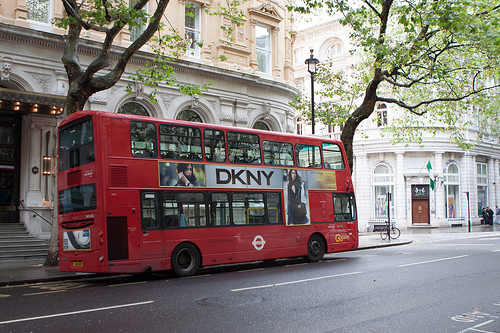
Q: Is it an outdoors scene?
A: Yes, it is outdoors.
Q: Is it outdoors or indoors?
A: It is outdoors.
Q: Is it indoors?
A: No, it is outdoors.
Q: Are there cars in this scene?
A: No, there are no cars.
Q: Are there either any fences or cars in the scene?
A: No, there are no cars or fences.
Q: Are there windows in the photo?
A: Yes, there is a window.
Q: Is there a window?
A: Yes, there is a window.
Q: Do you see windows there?
A: Yes, there is a window.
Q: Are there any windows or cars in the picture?
A: Yes, there is a window.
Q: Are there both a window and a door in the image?
A: Yes, there are both a window and a door.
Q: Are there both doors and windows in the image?
A: Yes, there are both a window and a door.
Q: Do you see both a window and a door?
A: Yes, there are both a window and a door.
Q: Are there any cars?
A: No, there are no cars.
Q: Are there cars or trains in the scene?
A: No, there are no cars or trains.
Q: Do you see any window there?
A: Yes, there is a window.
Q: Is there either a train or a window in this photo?
A: Yes, there is a window.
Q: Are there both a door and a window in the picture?
A: Yes, there are both a window and a door.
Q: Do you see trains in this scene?
A: No, there are no trains.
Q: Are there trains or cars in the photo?
A: No, there are no trains or cars.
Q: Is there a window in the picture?
A: Yes, there is a window.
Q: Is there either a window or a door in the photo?
A: Yes, there is a window.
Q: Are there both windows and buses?
A: Yes, there are both a window and a bus.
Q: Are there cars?
A: No, there are no cars.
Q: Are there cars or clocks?
A: No, there are no cars or clocks.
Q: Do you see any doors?
A: Yes, there is a door.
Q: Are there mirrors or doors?
A: Yes, there is a door.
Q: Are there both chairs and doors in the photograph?
A: No, there is a door but no chairs.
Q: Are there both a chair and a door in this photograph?
A: No, there is a door but no chairs.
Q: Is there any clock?
A: No, there are no clocks.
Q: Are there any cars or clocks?
A: No, there are no clocks or cars.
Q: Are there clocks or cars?
A: No, there are no clocks or cars.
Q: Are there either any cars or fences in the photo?
A: No, there are no cars or fences.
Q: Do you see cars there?
A: No, there are no cars.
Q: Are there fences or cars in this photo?
A: No, there are no cars or fences.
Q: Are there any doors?
A: Yes, there is a door.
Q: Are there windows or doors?
A: Yes, there is a door.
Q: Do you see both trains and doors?
A: No, there is a door but no trains.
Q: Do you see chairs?
A: No, there are no chairs.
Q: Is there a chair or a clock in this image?
A: No, there are no chairs or clocks.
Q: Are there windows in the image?
A: Yes, there is a window.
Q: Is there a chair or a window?
A: Yes, there is a window.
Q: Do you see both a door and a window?
A: Yes, there are both a window and a door.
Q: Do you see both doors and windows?
A: Yes, there are both a window and a door.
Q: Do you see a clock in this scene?
A: No, there are no clocks.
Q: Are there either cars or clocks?
A: No, there are no clocks or cars.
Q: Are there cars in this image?
A: No, there are no cars.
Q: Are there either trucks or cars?
A: No, there are no cars or trucks.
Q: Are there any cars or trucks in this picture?
A: No, there are no cars or trucks.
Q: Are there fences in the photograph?
A: No, there are no fences.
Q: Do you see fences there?
A: No, there are no fences.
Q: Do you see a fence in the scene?
A: No, there are no fences.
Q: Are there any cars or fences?
A: No, there are no fences or cars.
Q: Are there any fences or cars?
A: No, there are no fences or cars.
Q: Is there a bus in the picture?
A: Yes, there is a bus.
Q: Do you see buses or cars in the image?
A: Yes, there is a bus.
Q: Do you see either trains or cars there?
A: No, there are no cars or trains.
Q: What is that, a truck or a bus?
A: That is a bus.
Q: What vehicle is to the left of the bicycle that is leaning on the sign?
A: The vehicle is a bus.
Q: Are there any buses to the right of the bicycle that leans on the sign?
A: No, the bus is to the left of the bicycle.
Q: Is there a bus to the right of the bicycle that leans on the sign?
A: No, the bus is to the left of the bicycle.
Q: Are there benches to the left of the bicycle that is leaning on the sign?
A: No, there is a bus to the left of the bicycle.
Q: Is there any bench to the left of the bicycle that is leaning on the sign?
A: No, there is a bus to the left of the bicycle.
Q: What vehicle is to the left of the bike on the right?
A: The vehicle is a bus.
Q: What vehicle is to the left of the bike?
A: The vehicle is a bus.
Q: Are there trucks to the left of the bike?
A: No, there is a bus to the left of the bike.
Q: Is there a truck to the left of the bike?
A: No, there is a bus to the left of the bike.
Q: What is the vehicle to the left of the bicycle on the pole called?
A: The vehicle is a bus.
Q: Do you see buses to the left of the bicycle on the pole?
A: Yes, there is a bus to the left of the bicycle.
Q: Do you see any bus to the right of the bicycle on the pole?
A: No, the bus is to the left of the bicycle.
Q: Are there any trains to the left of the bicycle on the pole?
A: No, there is a bus to the left of the bicycle.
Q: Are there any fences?
A: No, there are no fences.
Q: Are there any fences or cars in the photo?
A: No, there are no fences or cars.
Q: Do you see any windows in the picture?
A: Yes, there are windows.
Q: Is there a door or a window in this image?
A: Yes, there are windows.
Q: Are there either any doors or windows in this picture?
A: Yes, there are windows.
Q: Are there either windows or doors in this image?
A: Yes, there are windows.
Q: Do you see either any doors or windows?
A: Yes, there are windows.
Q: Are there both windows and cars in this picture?
A: No, there are windows but no cars.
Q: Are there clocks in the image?
A: No, there are no clocks.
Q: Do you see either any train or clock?
A: No, there are no clocks or trains.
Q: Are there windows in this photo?
A: Yes, there is a window.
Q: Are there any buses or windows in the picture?
A: Yes, there is a window.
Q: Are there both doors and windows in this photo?
A: Yes, there are both a window and doors.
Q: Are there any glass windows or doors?
A: Yes, there is a glass window.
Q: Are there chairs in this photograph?
A: No, there are no chairs.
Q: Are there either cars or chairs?
A: No, there are no chairs or cars.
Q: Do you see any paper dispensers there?
A: No, there are no paper dispensers.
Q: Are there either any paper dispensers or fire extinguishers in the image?
A: No, there are no paper dispensers or fire extinguishers.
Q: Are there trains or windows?
A: Yes, there is a window.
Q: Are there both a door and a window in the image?
A: Yes, there are both a window and a door.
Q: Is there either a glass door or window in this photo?
A: Yes, there is a glass window.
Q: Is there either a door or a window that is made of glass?
A: Yes, the window is made of glass.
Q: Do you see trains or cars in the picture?
A: No, there are no cars or trains.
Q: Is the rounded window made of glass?
A: Yes, the window is made of glass.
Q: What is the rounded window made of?
A: The window is made of glass.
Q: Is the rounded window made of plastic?
A: No, the window is made of glass.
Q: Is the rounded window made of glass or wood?
A: The window is made of glass.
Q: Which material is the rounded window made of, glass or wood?
A: The window is made of glass.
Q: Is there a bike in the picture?
A: Yes, there is a bike.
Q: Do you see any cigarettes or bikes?
A: Yes, there is a bike.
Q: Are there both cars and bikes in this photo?
A: No, there is a bike but no cars.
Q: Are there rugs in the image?
A: No, there are no rugs.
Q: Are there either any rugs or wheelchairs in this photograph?
A: No, there are no rugs or wheelchairs.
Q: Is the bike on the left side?
A: No, the bike is on the right of the image.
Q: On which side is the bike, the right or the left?
A: The bike is on the right of the image.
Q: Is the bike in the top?
A: No, the bike is in the bottom of the image.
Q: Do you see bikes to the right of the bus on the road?
A: Yes, there is a bike to the right of the bus.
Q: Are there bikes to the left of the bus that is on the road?
A: No, the bike is to the right of the bus.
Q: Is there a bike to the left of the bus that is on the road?
A: No, the bike is to the right of the bus.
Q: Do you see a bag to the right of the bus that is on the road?
A: No, there is a bike to the right of the bus.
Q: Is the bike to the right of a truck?
A: No, the bike is to the right of the bus.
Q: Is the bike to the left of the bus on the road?
A: No, the bike is to the right of the bus.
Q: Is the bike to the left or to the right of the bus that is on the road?
A: The bike is to the right of the bus.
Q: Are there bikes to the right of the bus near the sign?
A: Yes, there is a bike to the right of the bus.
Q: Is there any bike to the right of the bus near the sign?
A: Yes, there is a bike to the right of the bus.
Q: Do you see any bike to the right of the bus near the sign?
A: Yes, there is a bike to the right of the bus.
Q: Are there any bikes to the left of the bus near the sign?
A: No, the bike is to the right of the bus.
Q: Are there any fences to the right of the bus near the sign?
A: No, there is a bike to the right of the bus.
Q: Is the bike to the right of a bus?
A: Yes, the bike is to the right of a bus.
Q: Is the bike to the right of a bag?
A: No, the bike is to the right of a bus.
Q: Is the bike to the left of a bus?
A: No, the bike is to the right of a bus.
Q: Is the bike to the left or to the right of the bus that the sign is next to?
A: The bike is to the right of the bus.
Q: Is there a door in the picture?
A: Yes, there is a door.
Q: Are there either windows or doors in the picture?
A: Yes, there is a door.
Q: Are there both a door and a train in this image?
A: No, there is a door but no trains.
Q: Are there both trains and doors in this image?
A: No, there is a door but no trains.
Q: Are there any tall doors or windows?
A: Yes, there is a tall door.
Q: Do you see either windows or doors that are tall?
A: Yes, the door is tall.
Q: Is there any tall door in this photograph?
A: Yes, there is a tall door.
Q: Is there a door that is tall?
A: Yes, there is a door that is tall.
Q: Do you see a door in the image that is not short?
A: Yes, there is a tall door.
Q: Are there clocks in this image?
A: No, there are no clocks.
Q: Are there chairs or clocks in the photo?
A: No, there are no clocks or chairs.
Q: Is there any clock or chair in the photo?
A: No, there are no clocks or chairs.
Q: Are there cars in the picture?
A: No, there are no cars.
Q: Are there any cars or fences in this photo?
A: No, there are no cars or fences.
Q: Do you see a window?
A: Yes, there is a window.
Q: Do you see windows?
A: Yes, there is a window.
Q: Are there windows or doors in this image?
A: Yes, there is a window.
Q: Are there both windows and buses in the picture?
A: Yes, there are both a window and a bus.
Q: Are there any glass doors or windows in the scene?
A: Yes, there is a glass window.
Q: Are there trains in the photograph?
A: No, there are no trains.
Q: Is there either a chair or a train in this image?
A: No, there are no trains or chairs.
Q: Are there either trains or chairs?
A: No, there are no trains or chairs.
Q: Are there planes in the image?
A: No, there are no planes.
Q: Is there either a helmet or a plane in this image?
A: No, there are no airplanes or helmets.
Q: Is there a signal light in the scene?
A: No, there are no traffic lights.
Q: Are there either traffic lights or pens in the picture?
A: No, there are no traffic lights or pens.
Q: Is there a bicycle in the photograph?
A: Yes, there is a bicycle.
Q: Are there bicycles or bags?
A: Yes, there is a bicycle.